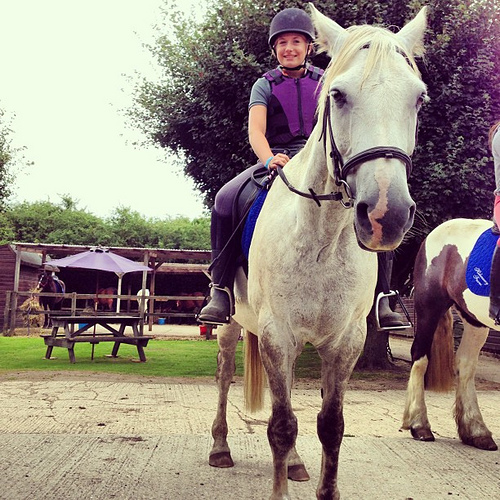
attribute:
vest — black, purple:
[235, 76, 357, 165]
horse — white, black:
[198, 78, 373, 494]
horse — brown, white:
[416, 198, 490, 438]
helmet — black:
[242, 5, 306, 39]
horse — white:
[211, 36, 395, 391]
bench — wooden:
[56, 311, 190, 359]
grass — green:
[14, 338, 228, 359]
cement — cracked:
[39, 381, 188, 456]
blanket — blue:
[225, 180, 293, 261]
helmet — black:
[260, 3, 320, 54]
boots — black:
[180, 260, 231, 314]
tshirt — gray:
[226, 65, 330, 161]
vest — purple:
[235, 84, 371, 168]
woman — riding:
[210, 21, 357, 165]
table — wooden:
[34, 295, 169, 370]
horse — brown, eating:
[21, 262, 116, 340]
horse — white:
[129, 278, 183, 340]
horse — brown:
[83, 281, 127, 321]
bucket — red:
[178, 310, 258, 345]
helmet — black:
[252, 11, 352, 61]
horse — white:
[199, 2, 499, 402]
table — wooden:
[39, 290, 178, 385]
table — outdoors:
[56, 303, 207, 375]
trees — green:
[47, 210, 207, 271]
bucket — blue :
[144, 303, 184, 332]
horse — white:
[124, 43, 411, 420]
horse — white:
[112, 68, 447, 498]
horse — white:
[201, 22, 484, 456]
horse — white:
[153, 40, 433, 498]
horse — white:
[119, 18, 425, 487]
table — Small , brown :
[22, 257, 161, 375]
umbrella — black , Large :
[52, 240, 140, 316]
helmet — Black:
[252, 14, 315, 45]